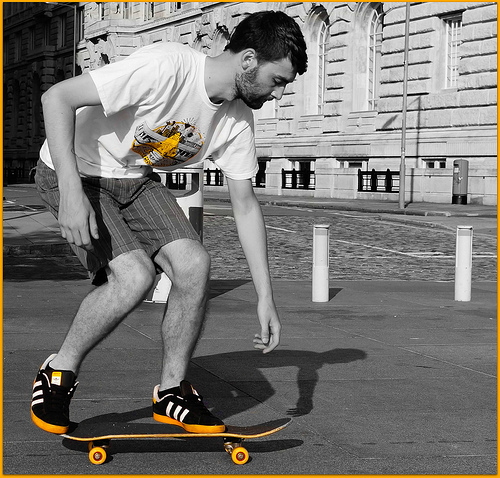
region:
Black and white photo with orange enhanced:
[5, 5, 498, 465]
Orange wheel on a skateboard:
[83, 445, 113, 463]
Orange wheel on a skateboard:
[230, 446, 253, 468]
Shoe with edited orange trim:
[23, 353, 87, 438]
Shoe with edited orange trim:
[147, 378, 229, 438]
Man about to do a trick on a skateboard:
[29, 8, 316, 465]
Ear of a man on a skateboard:
[237, 45, 254, 72]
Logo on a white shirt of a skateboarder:
[132, 118, 206, 168]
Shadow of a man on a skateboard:
[186, 338, 366, 424]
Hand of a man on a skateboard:
[45, 188, 105, 250]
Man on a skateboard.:
[26, 31, 401, 461]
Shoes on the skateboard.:
[32, 354, 167, 446]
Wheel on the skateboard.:
[178, 427, 275, 475]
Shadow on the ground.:
[180, 305, 400, 464]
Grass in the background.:
[286, 205, 489, 354]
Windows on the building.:
[339, 6, 406, 168]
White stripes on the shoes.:
[142, 369, 246, 475]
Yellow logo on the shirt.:
[128, 73, 247, 220]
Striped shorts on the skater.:
[37, 142, 287, 322]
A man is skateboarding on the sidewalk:
[16, 10, 377, 463]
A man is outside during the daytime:
[20, 0, 350, 471]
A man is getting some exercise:
[25, 2, 336, 472]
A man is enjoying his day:
[20, 6, 336, 467]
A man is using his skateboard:
[17, 10, 338, 463]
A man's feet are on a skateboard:
[11, 3, 323, 473]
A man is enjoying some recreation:
[15, 10, 348, 471]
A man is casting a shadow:
[17, 10, 384, 473]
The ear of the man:
[236, 47, 252, 68]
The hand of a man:
[56, 200, 96, 242]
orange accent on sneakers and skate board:
[18, 354, 298, 467]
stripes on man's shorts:
[31, 151, 203, 261]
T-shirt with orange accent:
[24, 39, 257, 182]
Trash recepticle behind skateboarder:
[136, 159, 204, 312]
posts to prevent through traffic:
[296, 218, 481, 310]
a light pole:
[398, 2, 415, 209]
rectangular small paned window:
[434, 14, 469, 86]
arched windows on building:
[293, 9, 386, 118]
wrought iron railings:
[163, 168, 413, 195]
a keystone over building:
[203, 2, 234, 34]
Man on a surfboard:
[49, 348, 305, 462]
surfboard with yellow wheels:
[197, 431, 273, 471]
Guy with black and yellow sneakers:
[141, 367, 236, 448]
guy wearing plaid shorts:
[86, 165, 191, 259]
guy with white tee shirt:
[58, 65, 253, 207]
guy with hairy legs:
[73, 279, 220, 357]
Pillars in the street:
[305, 210, 345, 309]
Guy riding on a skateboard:
[68, 130, 275, 448]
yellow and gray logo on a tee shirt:
[121, 102, 206, 195]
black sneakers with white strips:
[143, 361, 214, 441]